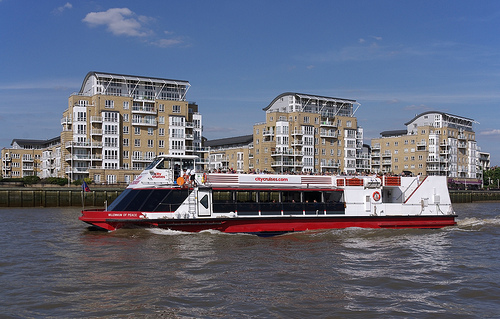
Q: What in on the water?
A: A ferry.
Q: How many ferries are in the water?
A: 1.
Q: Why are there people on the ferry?
A: To cross the river.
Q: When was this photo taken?
A: Daytime.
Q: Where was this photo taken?
A: On the water.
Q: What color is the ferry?
A: White and Red.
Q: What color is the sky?
A: Blue.